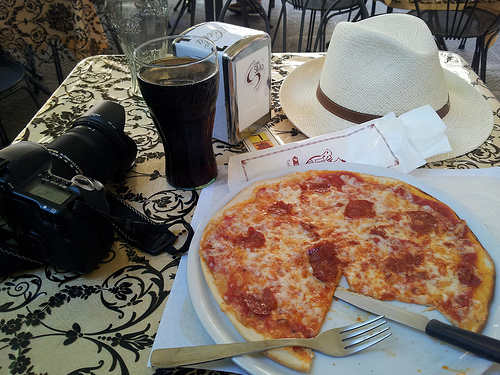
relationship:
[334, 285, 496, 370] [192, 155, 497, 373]
knife on plate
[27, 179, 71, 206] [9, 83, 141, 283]
display of camera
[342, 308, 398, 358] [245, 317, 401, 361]
silver prong of fork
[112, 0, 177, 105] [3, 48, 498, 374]
glass on table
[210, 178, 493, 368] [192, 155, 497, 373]
pizza on a plate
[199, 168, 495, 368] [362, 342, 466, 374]
pizza on plate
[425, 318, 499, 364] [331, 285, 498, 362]
handle on knife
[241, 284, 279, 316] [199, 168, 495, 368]
pepperoni on pizza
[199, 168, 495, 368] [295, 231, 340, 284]
pizza has pepperoni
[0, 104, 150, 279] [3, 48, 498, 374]
camera on table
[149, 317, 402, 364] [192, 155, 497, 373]
fork on plate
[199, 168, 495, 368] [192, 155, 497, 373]
pizza on plate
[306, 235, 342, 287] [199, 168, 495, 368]
pepperoni on pizza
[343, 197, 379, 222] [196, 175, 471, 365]
pepperoni on pizza